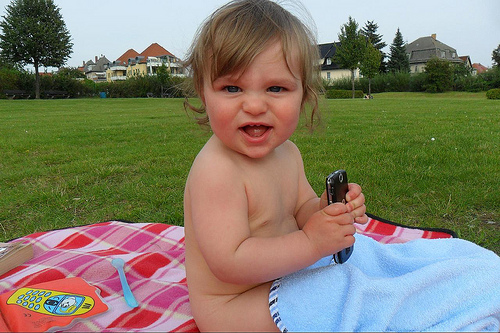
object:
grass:
[370, 93, 498, 216]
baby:
[181, 0, 369, 332]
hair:
[167, 1, 329, 133]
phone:
[323, 168, 359, 266]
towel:
[267, 231, 499, 333]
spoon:
[110, 254, 142, 310]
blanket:
[0, 220, 461, 332]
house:
[312, 41, 368, 87]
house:
[123, 42, 188, 83]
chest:
[237, 173, 302, 230]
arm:
[191, 173, 355, 286]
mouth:
[235, 119, 278, 145]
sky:
[380, 1, 498, 27]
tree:
[0, 0, 76, 101]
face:
[208, 52, 300, 157]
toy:
[0, 274, 113, 332]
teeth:
[246, 122, 268, 130]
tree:
[332, 16, 363, 100]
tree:
[360, 18, 388, 103]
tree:
[385, 29, 413, 92]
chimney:
[430, 34, 437, 43]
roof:
[398, 32, 458, 52]